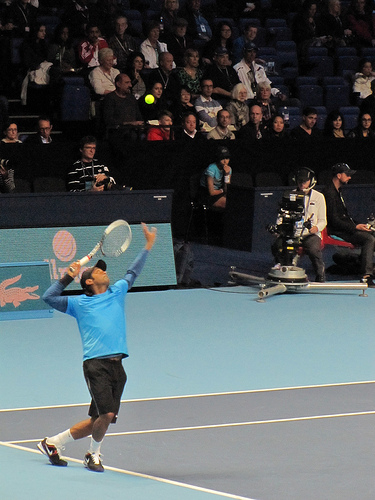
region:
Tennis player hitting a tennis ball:
[28, 78, 164, 486]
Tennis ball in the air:
[135, 86, 162, 113]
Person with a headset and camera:
[218, 159, 341, 299]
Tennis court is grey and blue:
[0, 286, 370, 499]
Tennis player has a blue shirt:
[31, 197, 175, 498]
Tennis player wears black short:
[22, 191, 190, 486]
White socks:
[41, 427, 114, 455]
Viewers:
[8, 11, 368, 199]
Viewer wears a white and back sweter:
[63, 138, 123, 198]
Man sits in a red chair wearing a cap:
[318, 152, 373, 291]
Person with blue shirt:
[25, 206, 173, 480]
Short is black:
[73, 355, 137, 420]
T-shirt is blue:
[56, 277, 139, 367]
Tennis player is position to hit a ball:
[27, 204, 174, 484]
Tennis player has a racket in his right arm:
[55, 208, 138, 284]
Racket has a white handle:
[57, 213, 137, 276]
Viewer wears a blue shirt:
[198, 142, 235, 214]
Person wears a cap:
[197, 144, 239, 215]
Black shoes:
[30, 443, 112, 473]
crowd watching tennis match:
[8, 7, 369, 206]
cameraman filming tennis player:
[231, 166, 353, 314]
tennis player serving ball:
[37, 201, 162, 475]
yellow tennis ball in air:
[132, 78, 188, 135]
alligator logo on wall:
[3, 270, 47, 319]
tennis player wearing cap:
[64, 249, 118, 297]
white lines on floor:
[3, 372, 353, 493]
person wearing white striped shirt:
[64, 132, 127, 198]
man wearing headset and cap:
[290, 163, 322, 202]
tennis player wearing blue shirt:
[38, 247, 162, 356]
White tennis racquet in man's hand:
[71, 192, 170, 238]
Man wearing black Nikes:
[39, 410, 149, 490]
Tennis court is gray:
[167, 362, 333, 479]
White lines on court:
[184, 368, 285, 487]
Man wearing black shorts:
[51, 333, 169, 398]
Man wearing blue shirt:
[45, 258, 126, 349]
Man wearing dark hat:
[76, 258, 108, 294]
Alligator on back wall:
[2, 260, 81, 346]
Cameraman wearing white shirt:
[268, 166, 353, 242]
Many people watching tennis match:
[77, 40, 255, 182]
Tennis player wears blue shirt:
[23, 201, 176, 479]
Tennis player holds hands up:
[29, 208, 187, 479]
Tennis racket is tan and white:
[66, 212, 137, 279]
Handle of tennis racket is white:
[61, 251, 93, 276]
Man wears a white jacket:
[232, 34, 286, 102]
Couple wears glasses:
[1, 112, 67, 169]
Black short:
[72, 357, 136, 422]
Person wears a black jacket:
[235, 96, 274, 138]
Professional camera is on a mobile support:
[220, 184, 372, 301]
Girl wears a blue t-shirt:
[196, 143, 239, 217]